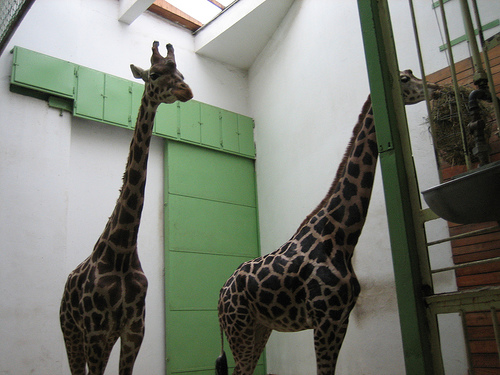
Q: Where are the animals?
A: In a room.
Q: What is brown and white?
A: The animals.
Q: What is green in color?
A: Walls.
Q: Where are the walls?
A: Behind the giraffes.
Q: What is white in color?
A: The wall.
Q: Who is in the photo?
A: No people.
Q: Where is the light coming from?
A: The ceiling.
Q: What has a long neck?
A: Both animals.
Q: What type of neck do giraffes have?
A: Long.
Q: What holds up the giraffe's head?
A: The neck.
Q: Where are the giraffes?
A: In a room.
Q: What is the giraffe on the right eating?
A: Hay.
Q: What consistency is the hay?
A: Dry.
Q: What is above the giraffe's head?
A: A skylight.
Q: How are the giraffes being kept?
A: Closed in.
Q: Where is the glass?
A: In ceiling.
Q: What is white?
A: The wall.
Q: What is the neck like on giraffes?
A: Long.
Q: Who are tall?
A: Giraffes.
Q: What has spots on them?
A: Giraffes.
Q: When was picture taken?
A: Daytime.